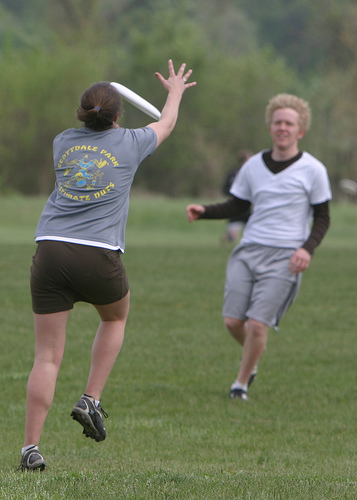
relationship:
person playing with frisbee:
[23, 58, 201, 466] [109, 78, 161, 122]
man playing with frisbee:
[182, 88, 334, 404] [109, 78, 161, 122]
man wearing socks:
[182, 88, 334, 404] [16, 441, 44, 457]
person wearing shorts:
[23, 58, 201, 466] [27, 236, 129, 317]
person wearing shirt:
[23, 58, 201, 466] [25, 123, 154, 255]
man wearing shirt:
[182, 88, 334, 404] [229, 149, 332, 248]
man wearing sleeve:
[182, 88, 334, 404] [301, 200, 328, 254]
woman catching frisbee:
[17, 57, 197, 475] [108, 75, 163, 122]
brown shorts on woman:
[20, 237, 129, 315] [17, 57, 197, 475]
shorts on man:
[217, 237, 306, 328] [182, 88, 334, 404]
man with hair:
[182, 88, 334, 404] [265, 93, 312, 129]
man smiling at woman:
[183, 88, 334, 357] [273, 131, 291, 141]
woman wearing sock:
[17, 57, 197, 475] [22, 443, 44, 454]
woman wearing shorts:
[30, 65, 173, 483] [27, 236, 129, 317]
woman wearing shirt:
[17, 57, 197, 475] [201, 130, 334, 255]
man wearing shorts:
[182, 88, 334, 404] [223, 245, 297, 319]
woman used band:
[17, 57, 197, 475] [91, 105, 103, 113]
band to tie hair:
[91, 105, 103, 113] [70, 78, 126, 131]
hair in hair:
[70, 78, 126, 131] [78, 81, 123, 127]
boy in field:
[197, 95, 338, 290] [19, 207, 337, 493]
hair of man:
[260, 88, 316, 134] [182, 88, 334, 404]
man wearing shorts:
[182, 88, 334, 404] [217, 238, 300, 334]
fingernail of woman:
[153, 70, 159, 76] [0, 55, 197, 469]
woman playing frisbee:
[17, 57, 197, 475] [100, 58, 194, 124]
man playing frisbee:
[182, 88, 334, 404] [109, 78, 161, 122]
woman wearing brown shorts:
[17, 57, 197, 475] [28, 237, 128, 315]